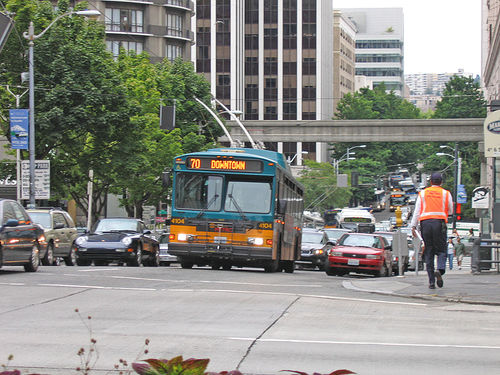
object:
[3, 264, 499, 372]
road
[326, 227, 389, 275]
vehicle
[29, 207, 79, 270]
vehicle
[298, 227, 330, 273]
vehicle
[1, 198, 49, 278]
vehicle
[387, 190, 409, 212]
vehicle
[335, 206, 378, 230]
vehicle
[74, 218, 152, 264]
cars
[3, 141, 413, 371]
going downtown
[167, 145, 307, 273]
green and yellow bus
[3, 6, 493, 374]
downtown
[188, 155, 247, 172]
neon bus sign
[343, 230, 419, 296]
next to curb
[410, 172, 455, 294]
man wearing orange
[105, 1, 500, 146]
highrise buildings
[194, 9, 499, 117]
background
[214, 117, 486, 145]
monor rail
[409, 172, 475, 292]
people walking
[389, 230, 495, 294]
sidewalk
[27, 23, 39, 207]
light post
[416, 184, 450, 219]
orange vest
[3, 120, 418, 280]
with cars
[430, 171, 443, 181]
hat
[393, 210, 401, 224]
yellow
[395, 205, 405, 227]
meter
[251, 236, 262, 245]
head lights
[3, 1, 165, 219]
green trees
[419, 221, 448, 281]
dark pants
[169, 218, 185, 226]
yellow writing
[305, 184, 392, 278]
near bus